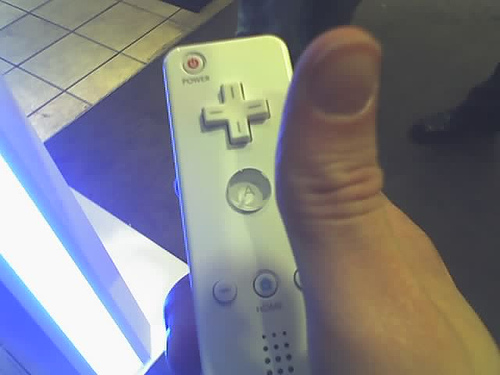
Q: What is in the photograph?
A: A remote control.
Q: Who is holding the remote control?
A: A person.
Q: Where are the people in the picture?
A: In a room.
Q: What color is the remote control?
A: White.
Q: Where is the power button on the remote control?
A: Top left side.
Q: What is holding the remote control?
A: Hand.